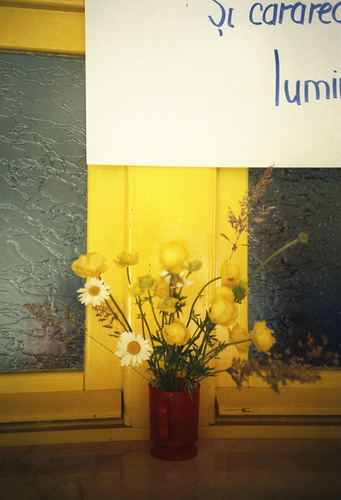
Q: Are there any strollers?
A: No, there are no strollers.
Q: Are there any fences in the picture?
A: No, there are no fences.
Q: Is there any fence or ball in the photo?
A: No, there are no fences or balls.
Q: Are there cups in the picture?
A: Yes, there is a cup.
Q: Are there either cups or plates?
A: Yes, there is a cup.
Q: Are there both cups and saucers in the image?
A: No, there is a cup but no saucers.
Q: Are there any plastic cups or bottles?
A: Yes, there is a plastic cup.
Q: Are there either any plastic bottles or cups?
A: Yes, there is a plastic cup.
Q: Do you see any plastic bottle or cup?
A: Yes, there is a plastic cup.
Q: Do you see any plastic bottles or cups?
A: Yes, there is a plastic cup.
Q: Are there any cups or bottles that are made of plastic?
A: Yes, the cup is made of plastic.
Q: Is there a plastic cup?
A: Yes, there is a cup that is made of plastic.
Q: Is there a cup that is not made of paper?
A: Yes, there is a cup that is made of plastic.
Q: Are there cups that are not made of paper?
A: Yes, there is a cup that is made of plastic.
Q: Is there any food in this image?
A: No, there is no food.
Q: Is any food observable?
A: No, there is no food.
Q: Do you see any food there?
A: No, there is no food.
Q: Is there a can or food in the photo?
A: No, there are no food or cans.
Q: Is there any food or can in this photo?
A: No, there are no food or cans.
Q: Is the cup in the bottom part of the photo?
A: Yes, the cup is in the bottom of the image.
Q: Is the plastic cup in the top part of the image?
A: No, the cup is in the bottom of the image.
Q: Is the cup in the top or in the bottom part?
A: The cup is in the bottom of the image.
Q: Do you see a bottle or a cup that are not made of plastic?
A: No, there is a cup but it is made of plastic.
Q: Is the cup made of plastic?
A: Yes, the cup is made of plastic.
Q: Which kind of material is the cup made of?
A: The cup is made of plastic.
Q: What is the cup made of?
A: The cup is made of plastic.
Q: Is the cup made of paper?
A: No, the cup is made of plastic.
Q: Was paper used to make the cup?
A: No, the cup is made of plastic.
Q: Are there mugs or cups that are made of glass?
A: No, there is a cup but it is made of plastic.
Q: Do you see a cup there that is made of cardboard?
A: No, there is a cup but it is made of plastic.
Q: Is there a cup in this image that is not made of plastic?
A: No, there is a cup but it is made of plastic.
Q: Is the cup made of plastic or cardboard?
A: The cup is made of plastic.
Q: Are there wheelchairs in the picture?
A: No, there are no wheelchairs.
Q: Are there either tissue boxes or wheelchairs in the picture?
A: No, there are no wheelchairs or tissue boxes.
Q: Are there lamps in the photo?
A: No, there are no lamps.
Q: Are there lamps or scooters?
A: No, there are no lamps or scooters.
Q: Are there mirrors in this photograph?
A: No, there are no mirrors.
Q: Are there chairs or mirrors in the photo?
A: No, there are no mirrors or chairs.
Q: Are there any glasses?
A: No, there are no glasses.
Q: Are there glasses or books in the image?
A: No, there are no glasses or books.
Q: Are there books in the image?
A: No, there are no books.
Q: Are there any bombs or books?
A: No, there are no books or bombs.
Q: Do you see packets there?
A: No, there are no packets.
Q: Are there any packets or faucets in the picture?
A: No, there are no packets or faucets.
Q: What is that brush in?
A: The brush is in the cup.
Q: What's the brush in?
A: The brush is in the cup.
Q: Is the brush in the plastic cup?
A: Yes, the brush is in the cup.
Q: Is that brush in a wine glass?
A: No, the brush is in the cup.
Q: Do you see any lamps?
A: No, there are no lamps.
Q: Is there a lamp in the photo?
A: No, there are no lamps.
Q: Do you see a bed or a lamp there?
A: No, there are no lamps or beds.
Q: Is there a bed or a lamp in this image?
A: No, there are no lamps or beds.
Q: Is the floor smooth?
A: Yes, the floor is smooth.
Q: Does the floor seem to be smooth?
A: Yes, the floor is smooth.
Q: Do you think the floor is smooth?
A: Yes, the floor is smooth.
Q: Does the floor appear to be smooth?
A: Yes, the floor is smooth.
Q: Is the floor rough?
A: No, the floor is smooth.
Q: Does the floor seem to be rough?
A: No, the floor is smooth.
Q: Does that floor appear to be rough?
A: No, the floor is smooth.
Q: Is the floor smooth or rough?
A: The floor is smooth.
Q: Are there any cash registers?
A: No, there are no cash registers.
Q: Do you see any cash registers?
A: No, there are no cash registers.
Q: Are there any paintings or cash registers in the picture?
A: No, there are no cash registers or paintings.